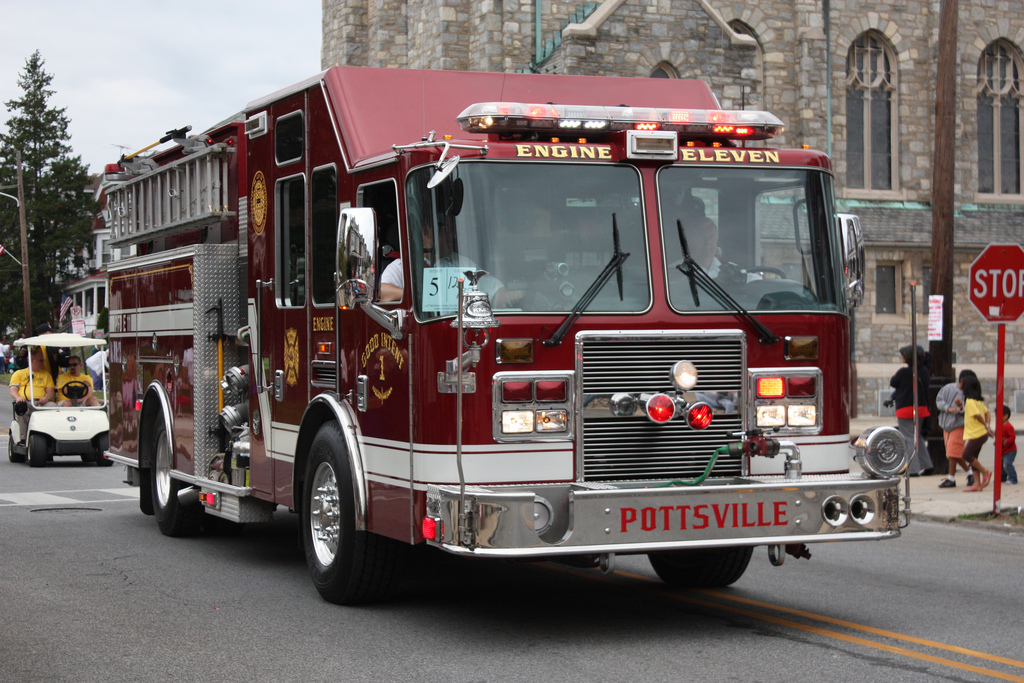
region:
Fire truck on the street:
[84, 59, 928, 610]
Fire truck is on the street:
[70, 54, 919, 618]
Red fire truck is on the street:
[83, 59, 900, 616]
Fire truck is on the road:
[71, 52, 919, 622]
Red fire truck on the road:
[95, 51, 931, 621]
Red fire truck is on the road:
[83, 51, 919, 617]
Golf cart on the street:
[5, 317, 129, 469]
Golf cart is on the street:
[4, 314, 137, 477]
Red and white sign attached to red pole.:
[976, 234, 1014, 501]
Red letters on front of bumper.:
[609, 497, 796, 535]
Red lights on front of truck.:
[641, 392, 712, 432]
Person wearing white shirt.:
[389, 243, 510, 292]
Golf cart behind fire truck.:
[2, 322, 136, 481]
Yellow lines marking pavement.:
[645, 562, 1013, 671]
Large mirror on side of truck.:
[316, 196, 380, 307]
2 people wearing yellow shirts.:
[9, 351, 112, 399]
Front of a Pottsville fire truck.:
[327, 114, 915, 551]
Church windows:
[836, 3, 1021, 203]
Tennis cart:
[1, 322, 115, 475]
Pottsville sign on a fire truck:
[614, 491, 792, 539]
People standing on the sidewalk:
[883, 336, 1021, 496]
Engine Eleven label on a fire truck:
[511, 139, 783, 169]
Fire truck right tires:
[135, 379, 421, 608]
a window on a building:
[841, 30, 906, 193]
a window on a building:
[966, 28, 1023, 222]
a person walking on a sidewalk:
[964, 351, 1000, 492]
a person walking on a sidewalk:
[976, 402, 1018, 479]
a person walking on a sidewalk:
[884, 326, 939, 470]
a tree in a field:
[7, 41, 116, 335]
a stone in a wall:
[794, 109, 811, 114]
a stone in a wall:
[811, 26, 832, 43]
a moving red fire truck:
[100, 64, 917, 606]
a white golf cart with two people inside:
[8, 331, 116, 465]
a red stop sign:
[967, 241, 1021, 516]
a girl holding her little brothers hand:
[960, 368, 1017, 489]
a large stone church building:
[319, 4, 1021, 415]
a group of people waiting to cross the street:
[890, 343, 1020, 489]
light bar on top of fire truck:
[454, 100, 788, 139]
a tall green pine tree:
[0, 49, 96, 340]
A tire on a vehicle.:
[294, 422, 396, 607]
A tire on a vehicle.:
[142, 405, 212, 541]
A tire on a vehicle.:
[645, 536, 754, 588]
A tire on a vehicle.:
[29, 430, 50, 465]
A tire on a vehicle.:
[92, 431, 113, 463]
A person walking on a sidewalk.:
[955, 365, 997, 487]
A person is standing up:
[882, 343, 933, 477]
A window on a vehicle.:
[404, 160, 652, 316]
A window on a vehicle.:
[656, 160, 850, 312]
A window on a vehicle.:
[271, 172, 310, 309]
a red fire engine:
[93, 63, 909, 607]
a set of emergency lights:
[457, 100, 783, 142]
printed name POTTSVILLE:
[614, 499, 795, 532]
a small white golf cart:
[5, 328, 105, 464]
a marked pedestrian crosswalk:
[2, 483, 140, 504]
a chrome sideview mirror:
[334, 208, 398, 336]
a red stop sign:
[960, 234, 1022, 353]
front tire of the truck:
[285, 423, 384, 595]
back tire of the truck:
[107, 395, 228, 547]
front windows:
[401, 133, 832, 343]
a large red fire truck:
[66, 62, 895, 587]